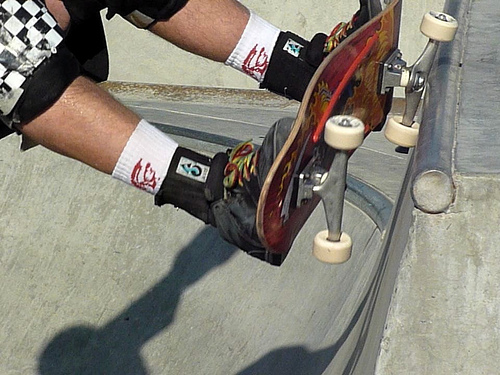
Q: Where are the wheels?
A: Under skateboard.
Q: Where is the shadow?
A: On ground.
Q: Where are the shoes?
A: Man's feet.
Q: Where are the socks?
A: Man's feet.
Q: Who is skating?
A: A man.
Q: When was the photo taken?
A: During skating.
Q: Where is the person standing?
A: On skateboard.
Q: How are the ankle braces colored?
A: In black.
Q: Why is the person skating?
A: For fun.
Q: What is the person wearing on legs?
A: White socks.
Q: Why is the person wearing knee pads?
A: Safety.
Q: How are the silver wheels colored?
A: In white and silver.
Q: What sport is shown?
A: Skateboarding.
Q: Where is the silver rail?
A: On top of the ramp.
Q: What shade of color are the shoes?
A: Black.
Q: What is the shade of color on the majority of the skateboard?
A: Red.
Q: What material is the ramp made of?
A: Concrete.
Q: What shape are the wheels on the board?
A: Round.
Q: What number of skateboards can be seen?
A: 1.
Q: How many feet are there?
A: Two.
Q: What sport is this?
A: Skateboarding.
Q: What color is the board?
A: Red.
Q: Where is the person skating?
A: At a skate park.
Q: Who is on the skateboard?
A: The man.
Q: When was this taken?
A: During the day.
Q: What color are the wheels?
A: White.